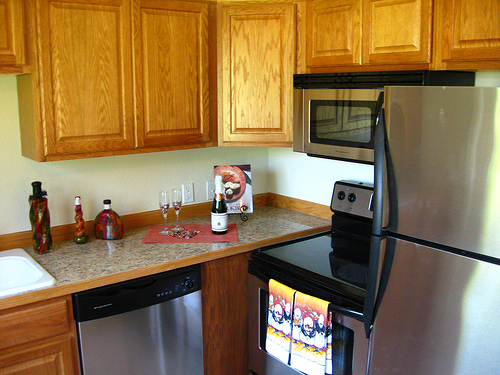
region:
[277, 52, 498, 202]
stainless steel microwave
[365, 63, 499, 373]
stainless steel fridge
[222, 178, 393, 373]
stainless steel stove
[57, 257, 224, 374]
stainless steel dish washer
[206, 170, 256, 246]
bottle of wine on counter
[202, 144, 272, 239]
recipe book on counter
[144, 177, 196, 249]
wine glasses on counter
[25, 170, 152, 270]
ornament on counter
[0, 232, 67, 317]
white sink in kitchen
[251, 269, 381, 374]
towels hanging over oven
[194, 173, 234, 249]
a wine bottle on a counter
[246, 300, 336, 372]
colorful towels on a oven handle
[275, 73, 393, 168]
a microwave oven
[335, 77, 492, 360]
a silver refrgerator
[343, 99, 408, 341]
black handles on a refigerator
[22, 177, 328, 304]
a granite counter top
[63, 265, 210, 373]
a silver and black dishwasher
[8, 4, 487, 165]
oak kitchen cabinets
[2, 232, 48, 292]
a kitchen sink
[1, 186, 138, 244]
decorative bottles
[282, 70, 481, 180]
stainless steel and black microwave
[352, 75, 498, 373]
stainless steel and black fridge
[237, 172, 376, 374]
stainless steel and black stove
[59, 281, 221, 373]
stainless steel and black dish washer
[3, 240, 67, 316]
white sink in counter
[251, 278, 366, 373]
two towels hanging over stove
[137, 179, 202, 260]
two wine glasses on counter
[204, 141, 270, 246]
recipe book on stand on counter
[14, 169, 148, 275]
ornaments on counter top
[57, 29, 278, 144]
wooden cabinets on the wall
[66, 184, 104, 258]
a swirly bottle of fruit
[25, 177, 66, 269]
a jar of peppers on the counter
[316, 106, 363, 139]
a window reflecting the kitchen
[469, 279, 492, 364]
light reflecting on the door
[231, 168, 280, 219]
a menu on a stand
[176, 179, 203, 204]
light socket in the wall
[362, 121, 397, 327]
black handles on the refrigerator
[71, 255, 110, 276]
a brown granite counter top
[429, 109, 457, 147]
smudges on the door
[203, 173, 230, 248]
a unopened bottle of champagne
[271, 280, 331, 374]
dish towels hanging on a handle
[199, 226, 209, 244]
a red placemat on the counter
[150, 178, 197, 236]
two wine glasses filled with candy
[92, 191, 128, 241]
peppers in a sealed jar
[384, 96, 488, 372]
a silver refrigerator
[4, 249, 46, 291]
a white sink next to the counter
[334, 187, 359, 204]
black knobs on the stove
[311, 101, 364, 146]
a window in a microwave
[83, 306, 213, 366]
a shiny silver dishwasher